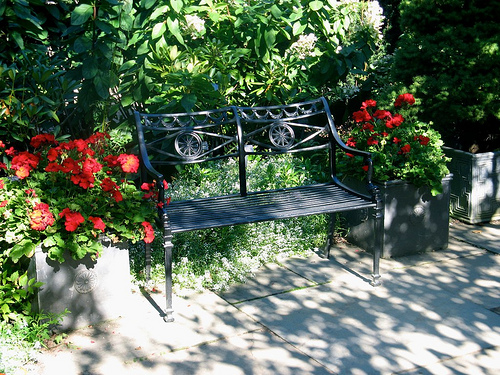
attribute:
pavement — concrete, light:
[2, 208, 497, 374]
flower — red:
[397, 87, 420, 119]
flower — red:
[417, 134, 429, 146]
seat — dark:
[131, 95, 393, 315]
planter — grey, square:
[8, 187, 152, 342]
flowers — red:
[332, 89, 429, 209]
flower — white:
[200, 183, 215, 198]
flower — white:
[214, 251, 233, 269]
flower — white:
[257, 239, 281, 261]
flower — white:
[274, 229, 294, 258]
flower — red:
[116, 150, 141, 175]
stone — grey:
[232, 278, 492, 371]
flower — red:
[13, 154, 38, 176]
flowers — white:
[127, 10, 392, 83]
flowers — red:
[331, 87, 415, 167]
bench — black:
[129, 95, 384, 324]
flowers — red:
[48, 154, 188, 254]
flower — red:
[30, 202, 55, 231]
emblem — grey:
[73, 268, 103, 298]